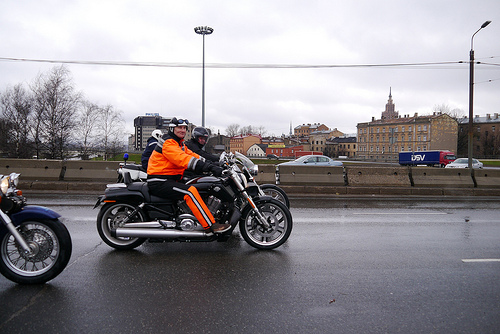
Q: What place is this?
A: It is a road.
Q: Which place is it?
A: It is a road.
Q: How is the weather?
A: It is cloudy.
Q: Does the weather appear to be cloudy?
A: Yes, it is cloudy.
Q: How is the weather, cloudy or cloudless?
A: It is cloudy.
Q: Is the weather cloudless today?
A: No, it is cloudy.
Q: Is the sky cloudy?
A: Yes, the sky is cloudy.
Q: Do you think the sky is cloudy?
A: Yes, the sky is cloudy.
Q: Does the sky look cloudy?
A: Yes, the sky is cloudy.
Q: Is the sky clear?
A: No, the sky is cloudy.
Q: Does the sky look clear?
A: No, the sky is cloudy.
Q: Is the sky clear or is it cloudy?
A: The sky is cloudy.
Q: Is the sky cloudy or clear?
A: The sky is cloudy.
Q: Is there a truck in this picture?
A: Yes, there is a truck.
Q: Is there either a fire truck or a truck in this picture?
A: Yes, there is a truck.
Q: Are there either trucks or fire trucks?
A: Yes, there is a truck.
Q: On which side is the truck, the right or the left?
A: The truck is on the right of the image.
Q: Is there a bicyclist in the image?
A: No, there are no cyclists.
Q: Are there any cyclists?
A: No, there are no cyclists.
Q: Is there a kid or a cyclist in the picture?
A: No, there are no cyclists or children.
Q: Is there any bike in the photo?
A: Yes, there is a bike.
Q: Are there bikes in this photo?
A: Yes, there is a bike.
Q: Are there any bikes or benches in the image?
A: Yes, there is a bike.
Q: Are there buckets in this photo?
A: No, there are no buckets.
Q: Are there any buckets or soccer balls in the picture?
A: No, there are no buckets or soccer balls.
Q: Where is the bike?
A: The bike is on the road.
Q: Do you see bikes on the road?
A: Yes, there is a bike on the road.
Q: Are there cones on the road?
A: No, there is a bike on the road.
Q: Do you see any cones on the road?
A: No, there is a bike on the road.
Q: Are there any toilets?
A: No, there are no toilets.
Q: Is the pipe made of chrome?
A: Yes, the pipe is made of chrome.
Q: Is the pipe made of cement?
A: No, the pipe is made of chrome.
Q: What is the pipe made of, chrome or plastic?
A: The pipe is made of chrome.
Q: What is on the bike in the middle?
A: The pipe is on the bike.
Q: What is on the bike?
A: The pipe is on the bike.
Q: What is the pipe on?
A: The pipe is on the bike.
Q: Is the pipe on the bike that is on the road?
A: Yes, the pipe is on the bike.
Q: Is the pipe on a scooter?
A: No, the pipe is on the bike.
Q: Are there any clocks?
A: No, there are no clocks.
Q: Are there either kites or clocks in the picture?
A: No, there are no clocks or kites.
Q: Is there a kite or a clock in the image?
A: No, there are no clocks or kites.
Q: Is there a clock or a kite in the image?
A: No, there are no clocks or kites.